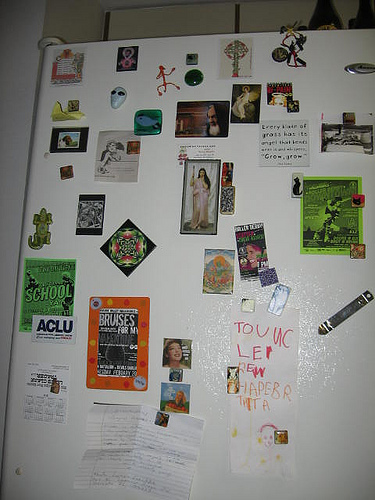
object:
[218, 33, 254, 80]
cross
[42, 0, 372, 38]
cabinetry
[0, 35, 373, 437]
magnets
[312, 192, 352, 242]
flyer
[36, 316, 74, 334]
aclu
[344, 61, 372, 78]
label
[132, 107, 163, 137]
magnet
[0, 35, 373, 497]
fridge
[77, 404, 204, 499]
school work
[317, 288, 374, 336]
can opener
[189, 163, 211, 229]
woman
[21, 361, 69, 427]
calendar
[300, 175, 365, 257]
flyer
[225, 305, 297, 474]
drawing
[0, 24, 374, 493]
refrigerator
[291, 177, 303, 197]
cat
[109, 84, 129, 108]
alien face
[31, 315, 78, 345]
sticker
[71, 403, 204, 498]
paper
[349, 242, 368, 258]
magnet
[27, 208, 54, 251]
lizard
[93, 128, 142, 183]
paper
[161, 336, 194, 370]
picture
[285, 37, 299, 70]
figure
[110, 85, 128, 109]
alien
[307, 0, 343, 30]
bottle